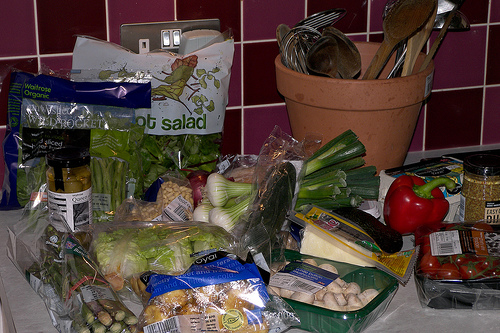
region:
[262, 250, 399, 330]
mushrooms in a green tray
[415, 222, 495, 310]
cherry tomatoes in a black tray with plastic wrap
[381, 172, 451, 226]
a red bell pepper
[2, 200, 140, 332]
a bunch of asparagus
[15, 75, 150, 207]
a bag of arugula or rocket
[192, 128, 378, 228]
a bunch of leeks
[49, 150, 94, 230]
a jar of pickles with a white label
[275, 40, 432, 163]
a flower pot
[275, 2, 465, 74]
cooking utensils in the flower pot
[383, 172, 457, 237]
red bell pepper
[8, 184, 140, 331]
package of asparagus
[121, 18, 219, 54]
light switch plate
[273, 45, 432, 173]
terra cotta pot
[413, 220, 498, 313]
container of cherry tomatoes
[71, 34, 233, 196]
bag of salad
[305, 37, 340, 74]
top of a wooden spoon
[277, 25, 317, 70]
top of a wire wisk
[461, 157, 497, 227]
glass jar with a black lid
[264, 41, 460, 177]
clay pot is orange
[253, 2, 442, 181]
cooking utensils in pot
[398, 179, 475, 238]
red pepper with stemg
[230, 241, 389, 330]
green container with mushrooms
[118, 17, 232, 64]
light switch behind bags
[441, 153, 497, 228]
small container with herbs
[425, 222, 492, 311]
black container with tomatoes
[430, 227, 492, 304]
small and red tomatoes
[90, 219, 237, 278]
lettuce in a pile of produce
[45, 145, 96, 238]
olives in a pile of produce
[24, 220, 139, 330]
asparagus in a pile of produce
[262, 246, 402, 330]
mushrooms in a pile of produce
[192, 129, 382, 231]
leeks in a pile of produce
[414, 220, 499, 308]
tomatoes in a pile of produce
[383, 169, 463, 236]
red pepper in a pile of produce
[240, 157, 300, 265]
pickle in a pile of produce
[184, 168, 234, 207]
onion in a pile of produce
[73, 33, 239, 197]
bag of salad in a pile of produce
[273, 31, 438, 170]
the pot is orange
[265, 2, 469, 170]
kitchen utensils in the pot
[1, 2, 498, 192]
the wall is tiled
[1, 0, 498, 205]
red squares on wall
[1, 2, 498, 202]
pink squares on wall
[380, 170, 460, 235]
red pepper on counter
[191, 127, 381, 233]
bulb onions on counter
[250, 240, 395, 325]
mushrooms on the counter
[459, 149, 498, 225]
condiment on the counter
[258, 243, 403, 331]
mushrooms in green container